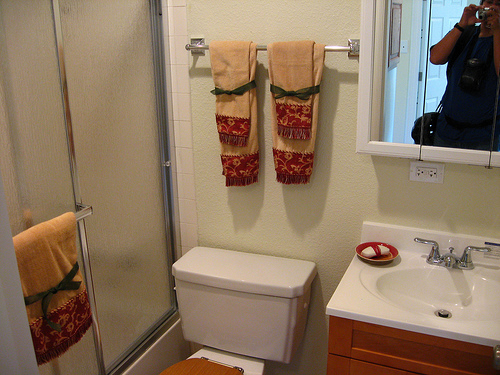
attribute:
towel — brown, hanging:
[197, 28, 272, 201]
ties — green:
[204, 74, 323, 109]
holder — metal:
[158, 33, 368, 65]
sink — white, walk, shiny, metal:
[150, 239, 342, 367]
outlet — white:
[409, 150, 451, 185]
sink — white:
[355, 230, 499, 338]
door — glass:
[36, 11, 172, 345]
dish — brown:
[351, 235, 391, 272]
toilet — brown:
[141, 354, 246, 373]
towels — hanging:
[207, 30, 332, 194]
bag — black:
[400, 96, 456, 159]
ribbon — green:
[193, 76, 280, 106]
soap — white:
[356, 238, 399, 262]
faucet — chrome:
[423, 215, 485, 270]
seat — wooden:
[171, 339, 258, 374]